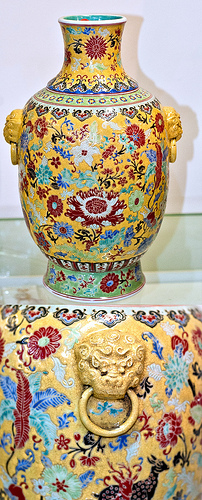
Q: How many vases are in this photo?
A: 1.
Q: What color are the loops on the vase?
A: Yellow.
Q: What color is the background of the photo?
A: White.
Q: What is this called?
A: A vase.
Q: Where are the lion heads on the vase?
A: Sides.